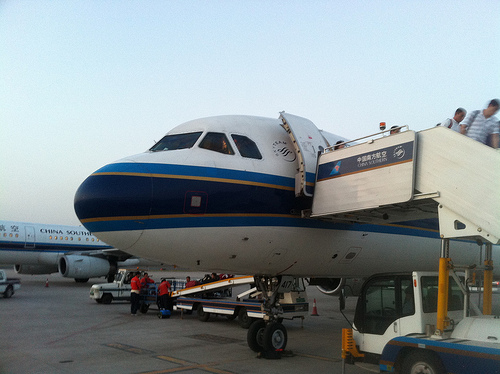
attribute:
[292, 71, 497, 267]
passenger — exiting, stair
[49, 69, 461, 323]
plane — air, blue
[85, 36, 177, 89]
sky — blue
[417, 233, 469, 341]
pole — yellow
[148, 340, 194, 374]
line — yellow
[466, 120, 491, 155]
shirt — striped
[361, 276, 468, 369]
truck — part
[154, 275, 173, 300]
shirt — red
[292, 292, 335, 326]
cone — white